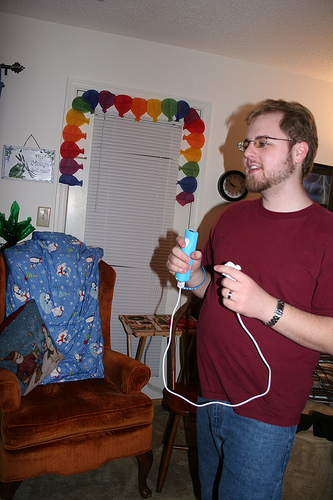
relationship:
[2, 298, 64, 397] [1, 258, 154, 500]
pillow on chair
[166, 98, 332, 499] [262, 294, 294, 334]
man has wrist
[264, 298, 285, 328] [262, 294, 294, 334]
watch on wrist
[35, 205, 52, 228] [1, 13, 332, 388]
light switch on wall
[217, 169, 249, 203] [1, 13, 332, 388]
clock on wall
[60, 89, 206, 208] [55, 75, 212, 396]
balloon decoration around window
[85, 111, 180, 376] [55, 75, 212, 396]
blinds covering window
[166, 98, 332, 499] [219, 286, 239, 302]
man has finger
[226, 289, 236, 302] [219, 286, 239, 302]
ring on finger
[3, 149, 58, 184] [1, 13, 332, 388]
sign hanging on wall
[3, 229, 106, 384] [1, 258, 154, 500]
blanket on chair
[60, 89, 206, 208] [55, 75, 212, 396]
balloon decoration on window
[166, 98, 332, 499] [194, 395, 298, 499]
man wearing jeans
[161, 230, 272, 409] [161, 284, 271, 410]
wii remote control has wire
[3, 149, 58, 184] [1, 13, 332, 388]
sign on wall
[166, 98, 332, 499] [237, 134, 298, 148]
man wearing eyeglasses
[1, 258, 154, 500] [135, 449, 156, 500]
chair has leg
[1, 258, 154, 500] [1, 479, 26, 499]
chair has leg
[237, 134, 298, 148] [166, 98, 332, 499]
eyeglasses are on man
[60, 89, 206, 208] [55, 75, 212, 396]
balloon decoration strung around window